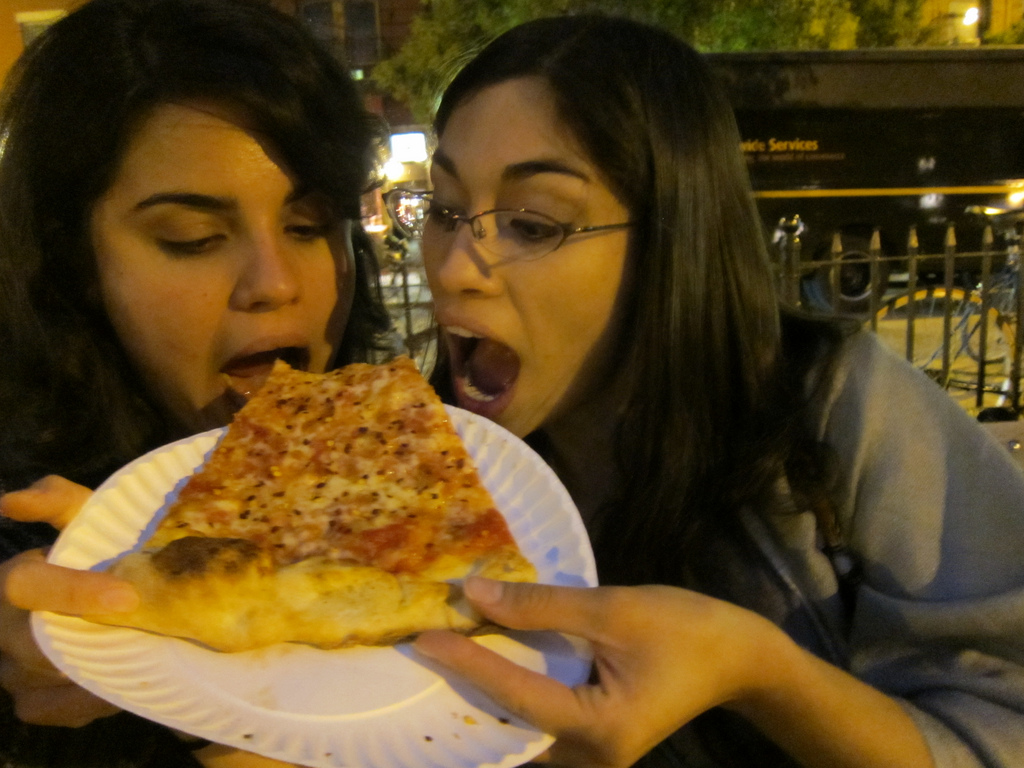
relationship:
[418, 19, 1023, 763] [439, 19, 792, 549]
girl has hair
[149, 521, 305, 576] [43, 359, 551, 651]
topping on pizza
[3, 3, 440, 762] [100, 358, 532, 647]
girl eating cheese pizza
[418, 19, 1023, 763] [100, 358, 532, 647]
girl eating cheese pizza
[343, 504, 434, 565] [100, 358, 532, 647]
sauce on cheese pizza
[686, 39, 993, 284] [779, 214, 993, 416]
van in back of fence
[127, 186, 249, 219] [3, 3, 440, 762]
eyebrow of girl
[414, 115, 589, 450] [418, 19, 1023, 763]
face of girl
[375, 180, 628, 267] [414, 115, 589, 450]
glasses on face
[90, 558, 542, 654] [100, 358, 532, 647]
crust on cheese pizza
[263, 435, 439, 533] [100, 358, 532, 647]
cheese on cheese pizza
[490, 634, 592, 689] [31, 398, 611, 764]
shadow on plate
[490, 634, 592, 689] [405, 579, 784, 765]
shadow of hand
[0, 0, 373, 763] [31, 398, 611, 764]
girl holding plate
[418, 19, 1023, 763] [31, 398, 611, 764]
girl holding plate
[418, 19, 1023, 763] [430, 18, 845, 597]
girl has hair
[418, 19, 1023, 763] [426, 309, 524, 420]
girl has mouth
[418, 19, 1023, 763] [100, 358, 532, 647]
girl sharing cheese pizza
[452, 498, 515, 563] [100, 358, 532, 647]
pepperoni on cheese pizza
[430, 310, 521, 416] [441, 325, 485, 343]
mouth with teeth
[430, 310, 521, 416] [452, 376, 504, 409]
mouth with teeth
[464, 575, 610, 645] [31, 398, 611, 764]
left thumb on plate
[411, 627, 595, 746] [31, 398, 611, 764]
finger on plate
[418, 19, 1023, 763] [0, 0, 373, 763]
girl eating with girl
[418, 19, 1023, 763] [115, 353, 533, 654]
girl eating pizza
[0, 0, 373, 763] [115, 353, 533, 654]
girl eating pizza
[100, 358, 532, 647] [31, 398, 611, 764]
cheese pizza on plate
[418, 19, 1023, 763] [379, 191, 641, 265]
girl wearing glasses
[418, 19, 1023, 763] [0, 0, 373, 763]
girl eating pizza with girl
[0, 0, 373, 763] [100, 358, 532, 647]
girl eating cheese pizza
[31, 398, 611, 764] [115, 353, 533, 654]
plate under pizza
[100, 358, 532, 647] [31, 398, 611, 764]
cheese pizza on top of plate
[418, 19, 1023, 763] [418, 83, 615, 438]
girl has face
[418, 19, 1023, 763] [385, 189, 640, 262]
girl wearing glasses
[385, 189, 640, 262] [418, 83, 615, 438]
glasses on face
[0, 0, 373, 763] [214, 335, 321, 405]
girl opening her mouth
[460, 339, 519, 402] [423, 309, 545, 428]
tongue in a mouth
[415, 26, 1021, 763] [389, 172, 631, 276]
girl with glasses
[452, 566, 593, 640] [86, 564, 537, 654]
left thumb touching crust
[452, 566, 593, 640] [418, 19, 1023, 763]
left thumb of girl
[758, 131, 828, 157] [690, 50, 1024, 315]
services painted on van